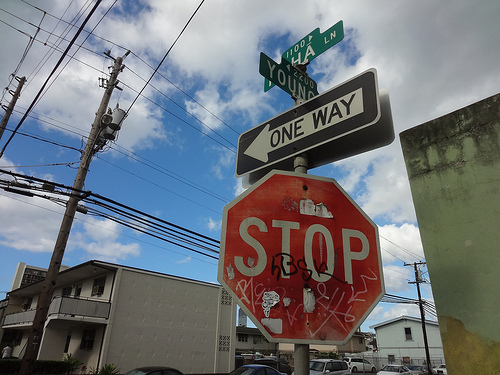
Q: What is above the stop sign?
A: A one way sign.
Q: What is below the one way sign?
A: A stop sign.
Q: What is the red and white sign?
A: A stop sign.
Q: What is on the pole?
A: Street signs.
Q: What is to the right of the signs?
A: A building.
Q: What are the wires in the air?
A: Utility lines.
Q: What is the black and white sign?
A: A one way sign.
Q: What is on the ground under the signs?
A: Cars.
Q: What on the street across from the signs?
A: A building.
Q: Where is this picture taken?
A: A street corner.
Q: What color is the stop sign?
A: Red.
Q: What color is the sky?
A: Blue.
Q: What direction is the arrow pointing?
A: Left.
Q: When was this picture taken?
A: Daytime.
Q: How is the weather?
A: Clear.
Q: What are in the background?
A: Buildings.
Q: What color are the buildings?
A: White.